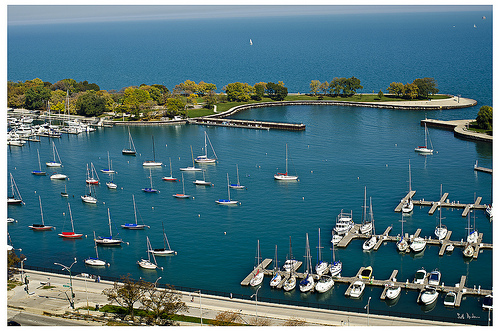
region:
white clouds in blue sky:
[18, 11, 58, 46]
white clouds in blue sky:
[52, 28, 102, 82]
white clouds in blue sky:
[197, 28, 229, 58]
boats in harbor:
[271, 153, 448, 280]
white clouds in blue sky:
[228, 16, 270, 54]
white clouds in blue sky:
[408, 39, 463, 66]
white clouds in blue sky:
[337, 9, 398, 60]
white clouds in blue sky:
[132, 21, 199, 65]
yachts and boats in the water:
[18, 107, 483, 302]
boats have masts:
[15, 130, 265, 275]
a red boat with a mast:
[52, 225, 78, 240]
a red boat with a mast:
[28, 220, 53, 232]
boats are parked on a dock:
[239, 246, 490, 318]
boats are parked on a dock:
[320, 219, 484, 262]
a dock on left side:
[179, 105, 309, 136]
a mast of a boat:
[281, 137, 293, 177]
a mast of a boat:
[176, 155, 187, 189]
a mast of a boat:
[102, 203, 118, 242]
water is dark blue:
[123, 26, 280, 73]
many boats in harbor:
[39, 126, 497, 317]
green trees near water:
[136, 71, 426, 121]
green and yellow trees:
[49, 73, 269, 126]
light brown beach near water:
[408, 83, 469, 123]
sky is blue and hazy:
[3, 1, 225, 29]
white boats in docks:
[264, 166, 497, 320]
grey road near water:
[1, 264, 339, 324]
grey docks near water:
[239, 256, 491, 308]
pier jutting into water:
[224, 118, 294, 144]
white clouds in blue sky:
[71, 28, 106, 52]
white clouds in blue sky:
[172, 5, 226, 42]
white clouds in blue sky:
[318, 25, 359, 50]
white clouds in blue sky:
[397, 31, 455, 76]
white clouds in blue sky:
[165, 35, 215, 67]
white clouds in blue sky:
[234, 25, 296, 77]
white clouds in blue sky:
[250, 31, 332, 78]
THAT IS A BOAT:
[82, 251, 107, 270]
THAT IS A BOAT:
[52, 221, 93, 248]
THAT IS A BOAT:
[25, 217, 62, 240]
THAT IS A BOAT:
[121, 208, 142, 237]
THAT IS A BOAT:
[76, 230, 132, 257]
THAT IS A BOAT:
[205, 197, 249, 210]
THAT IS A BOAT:
[172, 180, 189, 212]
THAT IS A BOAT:
[136, 180, 157, 202]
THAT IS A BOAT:
[116, 142, 154, 167]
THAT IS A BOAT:
[50, 163, 70, 193]